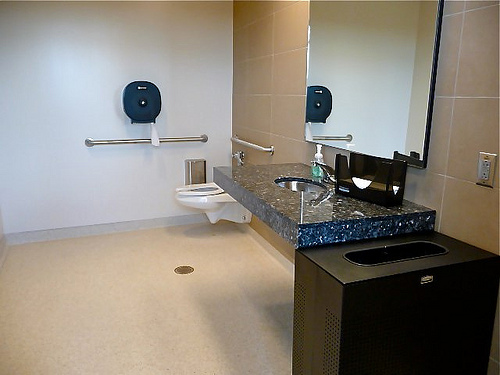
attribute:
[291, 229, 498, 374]
cabinet — black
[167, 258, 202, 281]
drain — round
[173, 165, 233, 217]
toilet — white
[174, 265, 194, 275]
drain — circular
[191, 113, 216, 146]
wall — black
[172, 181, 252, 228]
toilet — white, ceramic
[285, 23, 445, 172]
mirror — reflective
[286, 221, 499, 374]
waste bin — black, large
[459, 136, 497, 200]
outlet — electrical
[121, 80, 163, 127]
holder — see thru, black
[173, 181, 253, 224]
toilet — white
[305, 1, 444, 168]
mirror — square, large, frameless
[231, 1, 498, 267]
wall — restroom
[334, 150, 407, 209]
holder — large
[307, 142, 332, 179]
bottle — soap